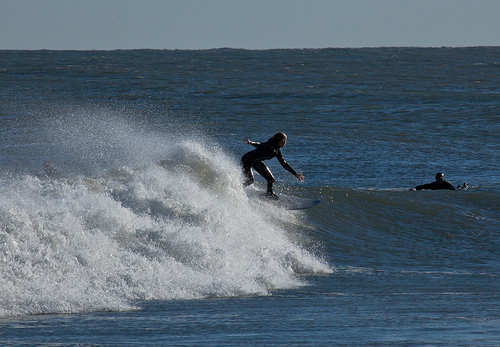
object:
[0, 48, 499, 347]
water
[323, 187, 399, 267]
wave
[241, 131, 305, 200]
person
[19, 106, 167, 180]
spray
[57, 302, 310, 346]
wave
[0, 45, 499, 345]
ocean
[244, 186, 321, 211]
surf board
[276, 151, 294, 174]
right arm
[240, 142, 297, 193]
wetsuit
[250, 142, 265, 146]
left arm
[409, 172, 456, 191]
man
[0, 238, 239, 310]
white wave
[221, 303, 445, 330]
surface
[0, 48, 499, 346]
sea